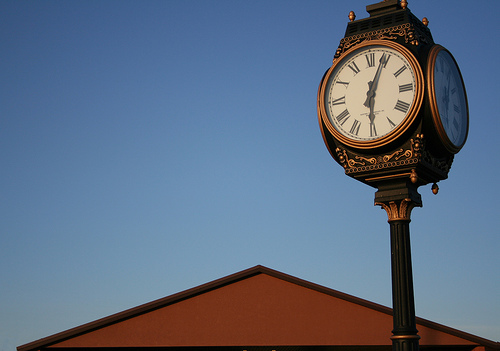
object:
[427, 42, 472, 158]
clocks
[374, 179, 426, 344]
pole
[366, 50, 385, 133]
hands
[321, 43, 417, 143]
clock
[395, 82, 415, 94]
numerals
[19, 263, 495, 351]
roof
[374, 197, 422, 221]
decotation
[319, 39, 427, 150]
border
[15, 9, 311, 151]
blue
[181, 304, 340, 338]
wall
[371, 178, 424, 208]
pedestal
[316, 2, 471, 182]
clock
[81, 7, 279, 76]
sky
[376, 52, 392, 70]
five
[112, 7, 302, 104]
portion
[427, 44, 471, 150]
face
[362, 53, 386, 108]
hand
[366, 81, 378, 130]
hand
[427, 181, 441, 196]
pieces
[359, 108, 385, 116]
letters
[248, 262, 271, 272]
peak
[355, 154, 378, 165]
scroll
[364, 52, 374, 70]
12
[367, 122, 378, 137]
roman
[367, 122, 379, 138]
6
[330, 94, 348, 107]
roman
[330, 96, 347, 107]
9